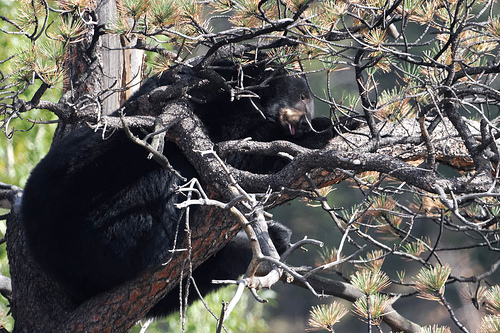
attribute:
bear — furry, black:
[227, 69, 311, 137]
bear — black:
[22, 51, 362, 319]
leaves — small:
[14, 0, 46, 28]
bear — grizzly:
[20, 63, 364, 289]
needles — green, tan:
[344, 271, 396, 295]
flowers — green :
[306, 202, 418, 319]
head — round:
[206, 35, 354, 185]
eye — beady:
[292, 82, 314, 101]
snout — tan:
[279, 99, 321, 130]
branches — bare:
[51, 20, 489, 321]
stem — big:
[65, 10, 144, 121]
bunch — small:
[311, 187, 402, 275]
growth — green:
[0, 1, 268, 329]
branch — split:
[3, 113, 499, 325]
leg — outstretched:
[240, 110, 368, 164]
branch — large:
[44, 115, 491, 329]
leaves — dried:
[15, 7, 498, 328]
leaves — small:
[347, 271, 392, 294]